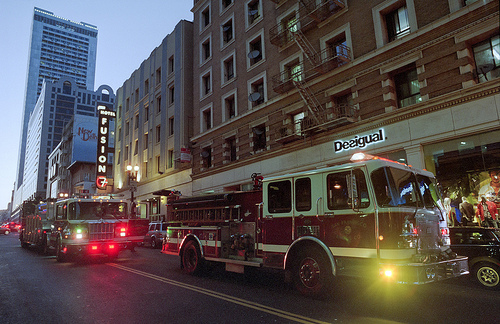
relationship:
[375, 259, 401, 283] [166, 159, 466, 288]
light on truck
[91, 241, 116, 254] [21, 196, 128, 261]
light on firetruck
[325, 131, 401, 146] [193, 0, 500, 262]
text on building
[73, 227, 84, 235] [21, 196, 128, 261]
light on firetruck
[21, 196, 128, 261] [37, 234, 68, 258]
firetruck has wheels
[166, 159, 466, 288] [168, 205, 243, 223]
firetruck has ladder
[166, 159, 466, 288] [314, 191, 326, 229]
truck has doorhandle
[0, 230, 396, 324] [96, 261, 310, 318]
street has divider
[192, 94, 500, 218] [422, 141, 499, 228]
store has window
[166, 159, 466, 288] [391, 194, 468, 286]
truck has headlights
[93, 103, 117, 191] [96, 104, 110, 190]
post says fusion7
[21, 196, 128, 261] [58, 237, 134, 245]
firetruck has bumper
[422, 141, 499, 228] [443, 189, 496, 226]
window with mannequins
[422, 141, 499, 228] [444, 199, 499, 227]
window with clothing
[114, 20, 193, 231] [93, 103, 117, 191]
building has sign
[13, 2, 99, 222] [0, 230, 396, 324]
building at street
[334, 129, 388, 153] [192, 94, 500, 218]
sign over store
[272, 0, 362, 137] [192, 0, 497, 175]
escape crosses windows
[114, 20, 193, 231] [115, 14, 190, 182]
building has stripes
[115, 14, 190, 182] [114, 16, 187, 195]
stripes between windows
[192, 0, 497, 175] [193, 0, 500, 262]
windows on floors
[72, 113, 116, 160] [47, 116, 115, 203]
advertisement on building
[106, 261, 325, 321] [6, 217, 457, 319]
stripe drawn on road